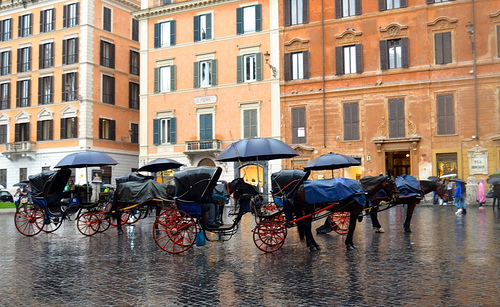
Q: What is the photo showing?
A: It is showing a road.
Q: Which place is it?
A: It is a road.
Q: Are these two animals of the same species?
A: Yes, all the animals are horses.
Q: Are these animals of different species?
A: No, all the animals are horses.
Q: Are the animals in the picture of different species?
A: No, all the animals are horses.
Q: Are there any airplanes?
A: No, there are no airplanes.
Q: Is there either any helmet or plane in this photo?
A: No, there are no airplanes or helmets.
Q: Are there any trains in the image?
A: No, there are no trains.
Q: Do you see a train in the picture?
A: No, there are no trains.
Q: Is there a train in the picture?
A: No, there are no trains.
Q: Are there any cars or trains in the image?
A: No, there are no trains or cars.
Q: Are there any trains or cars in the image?
A: No, there are no trains or cars.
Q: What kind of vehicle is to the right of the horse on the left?
A: The vehicle is a carriage.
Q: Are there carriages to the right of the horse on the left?
A: Yes, there is a carriage to the right of the horse.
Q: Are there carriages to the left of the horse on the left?
A: No, the carriage is to the right of the horse.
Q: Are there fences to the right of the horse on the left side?
A: No, there is a carriage to the right of the horse.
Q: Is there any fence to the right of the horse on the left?
A: No, there is a carriage to the right of the horse.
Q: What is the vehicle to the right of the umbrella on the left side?
A: The vehicle is a carriage.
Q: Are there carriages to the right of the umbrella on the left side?
A: Yes, there is a carriage to the right of the umbrella.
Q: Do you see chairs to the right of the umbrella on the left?
A: No, there is a carriage to the right of the umbrella.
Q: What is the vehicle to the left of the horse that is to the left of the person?
A: The vehicle is a carriage.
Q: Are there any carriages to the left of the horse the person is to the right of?
A: Yes, there is a carriage to the left of the horse.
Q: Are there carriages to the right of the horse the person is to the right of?
A: No, the carriage is to the left of the horse.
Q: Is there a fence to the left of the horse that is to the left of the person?
A: No, there is a carriage to the left of the horse.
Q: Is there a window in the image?
A: Yes, there is a window.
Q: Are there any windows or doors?
A: Yes, there is a window.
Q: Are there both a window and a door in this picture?
A: Yes, there are both a window and a door.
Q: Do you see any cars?
A: No, there are no cars.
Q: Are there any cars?
A: No, there are no cars.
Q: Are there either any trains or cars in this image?
A: No, there are no cars or trains.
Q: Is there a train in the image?
A: No, there are no trains.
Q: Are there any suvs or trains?
A: No, there are no trains or suvs.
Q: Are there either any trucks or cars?
A: No, there are no cars or trucks.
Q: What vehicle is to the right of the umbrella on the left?
A: The vehicle is a carriage.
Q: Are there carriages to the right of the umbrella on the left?
A: Yes, there is a carriage to the right of the umbrella.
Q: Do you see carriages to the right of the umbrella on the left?
A: Yes, there is a carriage to the right of the umbrella.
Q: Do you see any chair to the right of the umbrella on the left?
A: No, there is a carriage to the right of the umbrella.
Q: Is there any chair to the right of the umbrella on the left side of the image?
A: No, there is a carriage to the right of the umbrella.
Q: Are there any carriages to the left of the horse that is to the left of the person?
A: Yes, there is a carriage to the left of the horse.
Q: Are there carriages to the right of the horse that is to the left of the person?
A: No, the carriage is to the left of the horse.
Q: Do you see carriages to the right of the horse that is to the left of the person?
A: No, the carriage is to the left of the horse.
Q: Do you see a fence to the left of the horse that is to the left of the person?
A: No, there is a carriage to the left of the horse.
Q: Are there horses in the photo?
A: Yes, there is a horse.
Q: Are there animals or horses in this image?
A: Yes, there is a horse.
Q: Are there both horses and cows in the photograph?
A: No, there is a horse but no cows.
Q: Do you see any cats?
A: No, there are no cats.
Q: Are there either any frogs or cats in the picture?
A: No, there are no cats or frogs.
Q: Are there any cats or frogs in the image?
A: No, there are no cats or frogs.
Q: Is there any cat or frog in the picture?
A: No, there are no cats or frogs.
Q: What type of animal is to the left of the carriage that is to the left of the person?
A: The animal is a horse.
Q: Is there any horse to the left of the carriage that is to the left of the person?
A: Yes, there is a horse to the left of the carriage.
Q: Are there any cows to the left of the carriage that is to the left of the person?
A: No, there is a horse to the left of the carriage.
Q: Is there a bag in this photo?
A: No, there are no bags.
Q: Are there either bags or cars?
A: No, there are no bags or cars.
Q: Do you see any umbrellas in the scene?
A: Yes, there is an umbrella.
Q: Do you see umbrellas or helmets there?
A: Yes, there is an umbrella.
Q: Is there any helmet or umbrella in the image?
A: Yes, there is an umbrella.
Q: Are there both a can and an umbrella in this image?
A: No, there is an umbrella but no cans.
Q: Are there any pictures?
A: No, there are no pictures.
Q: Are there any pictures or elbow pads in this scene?
A: No, there are no pictures or elbow pads.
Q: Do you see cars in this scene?
A: No, there are no cars.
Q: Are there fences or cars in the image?
A: No, there are no cars or fences.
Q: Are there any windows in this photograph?
A: Yes, there is a window.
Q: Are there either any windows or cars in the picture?
A: Yes, there is a window.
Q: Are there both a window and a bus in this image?
A: No, there is a window but no buses.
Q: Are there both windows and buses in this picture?
A: No, there is a window but no buses.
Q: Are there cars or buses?
A: No, there are no cars or buses.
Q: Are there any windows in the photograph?
A: Yes, there is a window.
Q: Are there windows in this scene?
A: Yes, there is a window.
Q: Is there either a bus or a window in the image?
A: Yes, there is a window.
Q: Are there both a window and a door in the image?
A: Yes, there are both a window and a door.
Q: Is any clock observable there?
A: No, there are no clocks.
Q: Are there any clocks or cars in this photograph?
A: No, there are no clocks or cars.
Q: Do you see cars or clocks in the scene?
A: No, there are no clocks or cars.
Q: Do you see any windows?
A: Yes, there is a window.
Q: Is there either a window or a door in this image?
A: Yes, there is a window.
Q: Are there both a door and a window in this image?
A: Yes, there are both a window and a door.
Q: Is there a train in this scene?
A: No, there are no trains.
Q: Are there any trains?
A: No, there are no trains.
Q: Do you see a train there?
A: No, there are no trains.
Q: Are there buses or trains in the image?
A: No, there are no trains or buses.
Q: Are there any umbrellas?
A: Yes, there is an umbrella.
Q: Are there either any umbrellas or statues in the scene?
A: Yes, there is an umbrella.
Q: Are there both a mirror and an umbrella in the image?
A: No, there is an umbrella but no mirrors.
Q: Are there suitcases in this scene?
A: No, there are no suitcases.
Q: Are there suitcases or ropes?
A: No, there are no suitcases or ropes.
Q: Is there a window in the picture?
A: Yes, there is a window.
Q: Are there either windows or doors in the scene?
A: Yes, there is a window.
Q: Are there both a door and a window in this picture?
A: Yes, there are both a window and a door.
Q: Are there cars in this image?
A: No, there are no cars.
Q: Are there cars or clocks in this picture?
A: No, there are no cars or clocks.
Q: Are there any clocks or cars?
A: No, there are no cars or clocks.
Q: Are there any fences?
A: No, there are no fences.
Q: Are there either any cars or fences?
A: No, there are no fences or cars.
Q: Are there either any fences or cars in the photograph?
A: No, there are no fences or cars.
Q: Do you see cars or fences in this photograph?
A: No, there are no fences or cars.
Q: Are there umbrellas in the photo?
A: Yes, there is an umbrella.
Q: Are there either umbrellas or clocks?
A: Yes, there is an umbrella.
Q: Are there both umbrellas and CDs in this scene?
A: No, there is an umbrella but no cds.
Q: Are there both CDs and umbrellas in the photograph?
A: No, there is an umbrella but no cds.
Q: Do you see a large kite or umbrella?
A: Yes, there is a large umbrella.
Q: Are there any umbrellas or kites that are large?
A: Yes, the umbrella is large.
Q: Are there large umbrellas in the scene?
A: Yes, there is a large umbrella.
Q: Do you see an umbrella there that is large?
A: Yes, there is an umbrella that is large.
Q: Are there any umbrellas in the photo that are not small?
A: Yes, there is a large umbrella.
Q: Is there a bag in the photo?
A: No, there are no bags.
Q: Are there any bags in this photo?
A: No, there are no bags.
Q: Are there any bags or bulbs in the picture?
A: No, there are no bags or bulbs.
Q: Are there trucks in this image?
A: No, there are no trucks.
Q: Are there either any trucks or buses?
A: No, there are no trucks or buses.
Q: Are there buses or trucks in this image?
A: No, there are no trucks or buses.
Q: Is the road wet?
A: Yes, the road is wet.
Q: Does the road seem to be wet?
A: Yes, the road is wet.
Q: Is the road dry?
A: No, the road is wet.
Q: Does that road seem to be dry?
A: No, the road is wet.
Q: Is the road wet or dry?
A: The road is wet.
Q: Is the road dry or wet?
A: The road is wet.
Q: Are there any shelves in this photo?
A: No, there are no shelves.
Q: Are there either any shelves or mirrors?
A: No, there are no shelves or mirrors.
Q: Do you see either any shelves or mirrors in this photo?
A: No, there are no shelves or mirrors.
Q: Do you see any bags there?
A: No, there are no bags.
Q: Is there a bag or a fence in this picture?
A: No, there are no bags or fences.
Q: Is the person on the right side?
A: Yes, the person is on the right of the image.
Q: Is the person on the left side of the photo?
A: No, the person is on the right of the image.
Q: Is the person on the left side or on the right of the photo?
A: The person is on the right of the image.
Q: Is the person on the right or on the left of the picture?
A: The person is on the right of the image.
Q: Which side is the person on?
A: The person is on the right of the image.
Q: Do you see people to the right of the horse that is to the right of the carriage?
A: Yes, there is a person to the right of the horse.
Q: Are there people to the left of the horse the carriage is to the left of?
A: No, the person is to the right of the horse.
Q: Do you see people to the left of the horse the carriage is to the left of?
A: No, the person is to the right of the horse.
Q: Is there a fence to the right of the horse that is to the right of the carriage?
A: No, there is a person to the right of the horse.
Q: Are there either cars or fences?
A: No, there are no cars or fences.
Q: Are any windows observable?
A: Yes, there is a window.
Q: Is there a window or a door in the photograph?
A: Yes, there is a window.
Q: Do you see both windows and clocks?
A: No, there is a window but no clocks.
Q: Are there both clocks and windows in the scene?
A: No, there is a window but no clocks.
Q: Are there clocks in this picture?
A: No, there are no clocks.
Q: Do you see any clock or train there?
A: No, there are no clocks or trains.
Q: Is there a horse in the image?
A: Yes, there is a horse.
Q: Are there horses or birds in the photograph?
A: Yes, there is a horse.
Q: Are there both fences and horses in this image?
A: No, there is a horse but no fences.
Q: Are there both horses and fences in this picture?
A: No, there is a horse but no fences.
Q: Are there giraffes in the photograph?
A: No, there are no giraffes.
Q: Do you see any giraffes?
A: No, there are no giraffes.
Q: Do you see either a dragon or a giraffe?
A: No, there are no giraffes or dragons.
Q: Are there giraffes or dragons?
A: No, there are no giraffes or dragons.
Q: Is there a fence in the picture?
A: No, there are no fences.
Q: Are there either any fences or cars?
A: No, there are no fences or cars.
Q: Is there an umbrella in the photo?
A: Yes, there is an umbrella.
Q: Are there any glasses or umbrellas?
A: Yes, there is an umbrella.